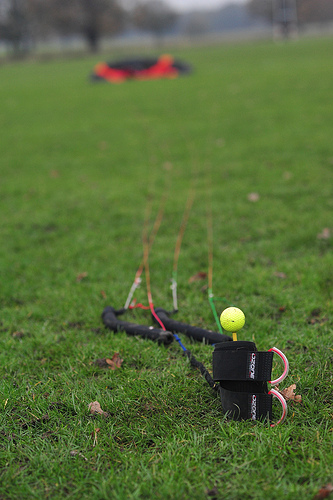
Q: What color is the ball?
A: Yellow.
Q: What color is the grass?
A: Green.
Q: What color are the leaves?
A: Brown.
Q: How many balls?
A: One.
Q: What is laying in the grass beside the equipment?
A: Leaves.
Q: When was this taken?
A: During the day.